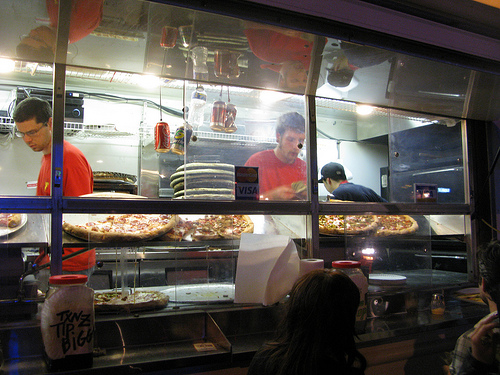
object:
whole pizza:
[63, 191, 180, 245]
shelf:
[0, 213, 467, 247]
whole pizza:
[164, 213, 256, 242]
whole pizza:
[318, 213, 383, 236]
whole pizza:
[375, 213, 419, 237]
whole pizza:
[88, 288, 170, 312]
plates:
[368, 273, 407, 281]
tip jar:
[40, 274, 97, 372]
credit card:
[233, 167, 260, 182]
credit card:
[233, 181, 259, 197]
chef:
[318, 163, 388, 203]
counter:
[0, 232, 469, 373]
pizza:
[0, 212, 23, 228]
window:
[183, 77, 309, 198]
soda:
[154, 121, 172, 153]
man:
[11, 96, 96, 288]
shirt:
[35, 141, 98, 272]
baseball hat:
[314, 162, 348, 184]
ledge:
[0, 338, 230, 374]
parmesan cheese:
[430, 305, 445, 315]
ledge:
[204, 283, 489, 356]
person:
[244, 267, 369, 374]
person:
[442, 239, 500, 374]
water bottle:
[184, 86, 206, 130]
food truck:
[0, 1, 499, 374]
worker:
[243, 112, 309, 237]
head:
[283, 268, 359, 344]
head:
[476, 242, 499, 305]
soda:
[170, 122, 191, 156]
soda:
[210, 98, 228, 132]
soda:
[224, 103, 238, 133]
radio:
[13, 85, 85, 137]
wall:
[0, 90, 390, 196]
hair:
[11, 97, 52, 126]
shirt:
[328, 179, 389, 203]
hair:
[321, 175, 347, 183]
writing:
[48, 307, 94, 351]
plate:
[160, 283, 237, 304]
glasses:
[14, 120, 49, 138]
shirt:
[241, 150, 309, 200]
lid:
[44, 273, 89, 285]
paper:
[234, 234, 301, 307]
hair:
[252, 268, 367, 374]